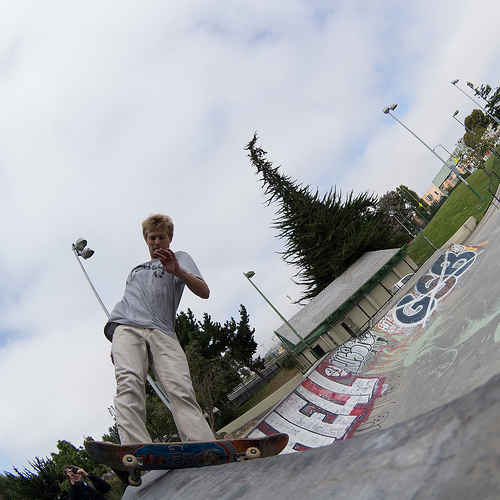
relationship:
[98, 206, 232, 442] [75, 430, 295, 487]
man standing on skateboard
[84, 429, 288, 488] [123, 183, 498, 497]
skateboard on edge of ramp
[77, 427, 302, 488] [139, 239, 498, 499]
giraffe on ramp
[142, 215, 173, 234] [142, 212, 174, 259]
hair on head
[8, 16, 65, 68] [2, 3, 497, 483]
clouds in sky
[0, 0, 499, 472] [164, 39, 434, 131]
clouds in sky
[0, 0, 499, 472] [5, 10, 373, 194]
clouds in sky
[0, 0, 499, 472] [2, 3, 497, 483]
clouds in sky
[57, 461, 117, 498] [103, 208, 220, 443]
person taking picture of skateboarder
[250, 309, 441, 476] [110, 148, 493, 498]
graffiti at skateboard park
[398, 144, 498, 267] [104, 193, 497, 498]
grassy area beside skateboard park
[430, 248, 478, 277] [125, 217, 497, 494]
letter on ground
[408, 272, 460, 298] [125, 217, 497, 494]
letter on ground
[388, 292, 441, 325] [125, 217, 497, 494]
letter on ground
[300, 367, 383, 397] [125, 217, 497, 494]
letter on ground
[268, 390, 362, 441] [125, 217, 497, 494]
letter on ground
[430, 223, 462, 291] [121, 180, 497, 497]
letter on ground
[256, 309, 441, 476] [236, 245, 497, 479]
graffiti on skate ramp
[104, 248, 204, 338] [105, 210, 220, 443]
shirt on skater